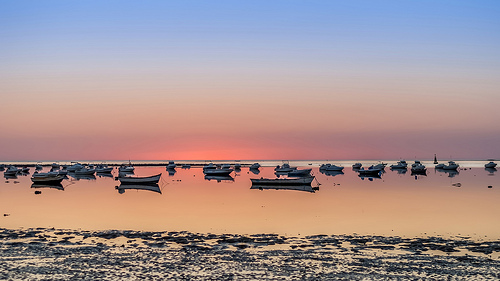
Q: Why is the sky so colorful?
A: The sun is setting.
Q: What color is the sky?
A: Blue.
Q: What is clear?
A: The sky.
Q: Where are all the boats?
A: In the water.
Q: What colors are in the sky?
A: Blue, purple, and orange.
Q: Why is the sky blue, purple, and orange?
A: The sun is setting.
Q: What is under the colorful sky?
A: Boats.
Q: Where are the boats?
A: In the ocean.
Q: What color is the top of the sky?
A: Blue.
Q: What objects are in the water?
A: Boats.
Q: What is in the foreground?
A: Sand.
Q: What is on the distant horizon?
A: Water.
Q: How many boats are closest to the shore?
A: Three.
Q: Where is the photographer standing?
A: On the beach.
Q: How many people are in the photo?
A: None.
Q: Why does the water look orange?
A: Reflecting the sun.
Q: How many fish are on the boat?
A: None.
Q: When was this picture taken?
A: Sunset.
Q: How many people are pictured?
A: None.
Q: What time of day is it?
A: Dusk.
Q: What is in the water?
A: Boats.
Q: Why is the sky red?
A: Sunset.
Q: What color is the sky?
A: Red.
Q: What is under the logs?
A: Sand.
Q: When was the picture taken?
A: Evening.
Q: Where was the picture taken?
A: The beach.